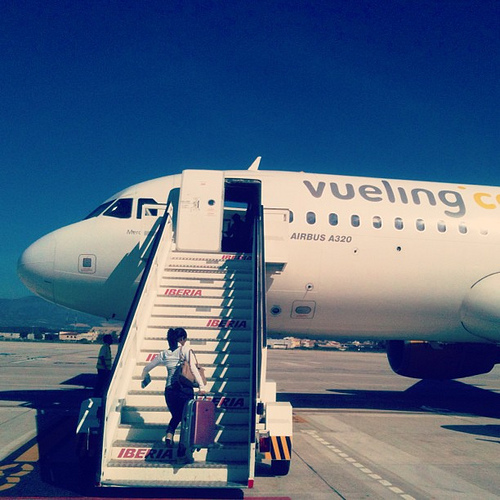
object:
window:
[305, 211, 316, 225]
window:
[372, 215, 382, 229]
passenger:
[141, 327, 207, 457]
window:
[327, 212, 338, 227]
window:
[350, 213, 361, 228]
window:
[393, 216, 405, 231]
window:
[436, 218, 447, 233]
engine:
[385, 339, 499, 379]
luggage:
[180, 390, 216, 452]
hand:
[197, 384, 205, 392]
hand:
[141, 368, 149, 380]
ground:
[378, 180, 414, 231]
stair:
[98, 204, 267, 488]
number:
[0, 455, 32, 493]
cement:
[0, 339, 499, 498]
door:
[176, 168, 226, 254]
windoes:
[303, 207, 490, 246]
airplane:
[16, 155, 499, 379]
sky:
[1, 1, 499, 301]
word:
[303, 178, 500, 218]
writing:
[437, 189, 466, 218]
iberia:
[163, 287, 203, 298]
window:
[136, 197, 159, 219]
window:
[102, 196, 133, 219]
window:
[81, 199, 114, 219]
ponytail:
[167, 326, 179, 352]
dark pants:
[163, 381, 194, 454]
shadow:
[0, 372, 499, 499]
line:
[300, 428, 418, 498]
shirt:
[140, 340, 205, 392]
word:
[205, 318, 247, 327]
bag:
[183, 350, 205, 386]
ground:
[0, 338, 499, 499]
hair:
[167, 326, 189, 352]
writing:
[471, 189, 498, 210]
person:
[95, 333, 115, 391]